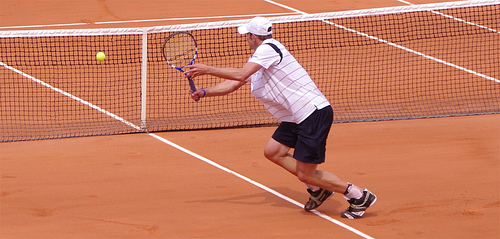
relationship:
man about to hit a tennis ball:
[187, 14, 377, 218] [96, 50, 106, 63]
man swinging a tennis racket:
[187, 14, 377, 218] [162, 31, 198, 97]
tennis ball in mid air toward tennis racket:
[96, 50, 106, 63] [162, 31, 198, 97]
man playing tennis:
[187, 14, 377, 218] [79, 12, 305, 124]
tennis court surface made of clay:
[2, 1, 500, 236] [32, 180, 133, 225]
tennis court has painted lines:
[2, 1, 500, 236] [162, 139, 252, 180]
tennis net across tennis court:
[1, 1, 498, 128] [2, 1, 500, 236]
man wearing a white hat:
[187, 14, 377, 218] [235, 15, 276, 39]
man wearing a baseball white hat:
[187, 14, 377, 218] [235, 15, 276, 39]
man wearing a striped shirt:
[187, 14, 377, 218] [248, 38, 331, 125]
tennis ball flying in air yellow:
[96, 50, 106, 63] [98, 52, 102, 58]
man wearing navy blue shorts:
[187, 14, 377, 218] [272, 104, 333, 164]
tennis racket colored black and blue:
[162, 31, 198, 97] [171, 56, 200, 86]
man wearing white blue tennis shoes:
[187, 14, 377, 218] [342, 187, 378, 219]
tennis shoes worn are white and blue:
[342, 187, 378, 219] [350, 201, 369, 220]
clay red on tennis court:
[32, 180, 133, 225] [2, 1, 500, 236]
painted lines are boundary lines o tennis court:
[162, 139, 252, 180] [2, 1, 500, 236]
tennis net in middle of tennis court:
[1, 1, 498, 128] [2, 1, 500, 236]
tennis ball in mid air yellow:
[96, 50, 106, 63] [98, 52, 102, 58]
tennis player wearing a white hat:
[187, 14, 377, 218] [235, 15, 276, 39]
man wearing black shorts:
[187, 14, 377, 218] [294, 104, 335, 163]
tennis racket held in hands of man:
[162, 31, 198, 97] [187, 14, 377, 218]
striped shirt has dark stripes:
[248, 38, 331, 125] [263, 41, 283, 65]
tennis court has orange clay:
[2, 1, 500, 236] [32, 180, 133, 225]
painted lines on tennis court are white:
[162, 139, 252, 180] [249, 178, 264, 187]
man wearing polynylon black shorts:
[187, 14, 377, 218] [294, 104, 335, 163]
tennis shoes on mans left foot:
[342, 187, 378, 219] [342, 182, 376, 220]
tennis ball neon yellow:
[96, 50, 106, 63] [98, 52, 102, 58]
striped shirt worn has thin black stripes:
[248, 38, 331, 125] [281, 74, 308, 101]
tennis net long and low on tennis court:
[1, 1, 498, 128] [2, 1, 500, 236]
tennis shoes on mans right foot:
[342, 187, 378, 219] [302, 176, 335, 211]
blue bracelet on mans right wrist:
[201, 87, 208, 98] [196, 83, 211, 103]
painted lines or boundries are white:
[162, 139, 252, 180] [249, 178, 264, 187]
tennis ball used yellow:
[96, 50, 106, 63] [98, 52, 102, 58]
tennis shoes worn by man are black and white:
[342, 187, 378, 219] [364, 187, 379, 204]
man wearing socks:
[187, 14, 377, 218] [346, 184, 364, 204]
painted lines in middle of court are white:
[162, 139, 252, 180] [222, 165, 250, 182]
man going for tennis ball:
[187, 14, 377, 218] [96, 50, 106, 63]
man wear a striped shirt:
[187, 14, 377, 218] [248, 38, 331, 125]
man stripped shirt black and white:
[187, 14, 377, 218] [364, 187, 379, 204]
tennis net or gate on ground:
[1, 1, 498, 128] [367, 104, 455, 132]